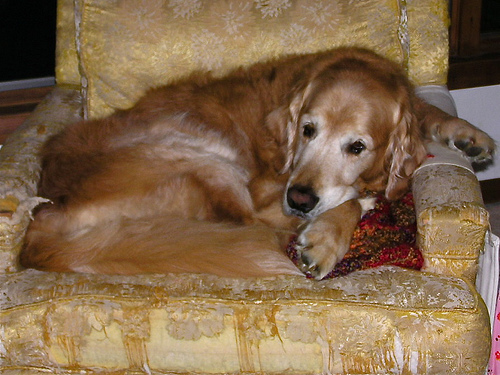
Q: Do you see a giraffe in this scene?
A: No, there are no giraffes.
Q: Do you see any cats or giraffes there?
A: No, there are no giraffes or cats.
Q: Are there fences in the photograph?
A: No, there are no fences.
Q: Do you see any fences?
A: No, there are no fences.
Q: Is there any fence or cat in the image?
A: No, there are no fences or cats.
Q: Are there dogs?
A: Yes, there is a dog.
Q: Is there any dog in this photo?
A: Yes, there is a dog.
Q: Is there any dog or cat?
A: Yes, there is a dog.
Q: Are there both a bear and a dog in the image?
A: No, there is a dog but no bears.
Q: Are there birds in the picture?
A: No, there are no birds.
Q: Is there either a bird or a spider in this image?
A: No, there are no birds or spiders.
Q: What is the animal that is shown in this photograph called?
A: The animal is a dog.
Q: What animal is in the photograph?
A: The animal is a dog.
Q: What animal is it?
A: The animal is a dog.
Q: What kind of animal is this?
A: This is a dog.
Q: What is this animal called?
A: This is a dog.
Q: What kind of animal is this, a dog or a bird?
A: This is a dog.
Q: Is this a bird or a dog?
A: This is a dog.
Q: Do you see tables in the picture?
A: Yes, there is a table.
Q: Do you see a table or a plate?
A: Yes, there is a table.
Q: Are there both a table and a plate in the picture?
A: No, there is a table but no plates.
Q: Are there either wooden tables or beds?
A: Yes, there is a wood table.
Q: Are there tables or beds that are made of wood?
A: Yes, the table is made of wood.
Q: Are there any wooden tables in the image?
A: Yes, there is a wood table.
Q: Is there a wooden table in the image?
A: Yes, there is a wood table.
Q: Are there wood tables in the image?
A: Yes, there is a wood table.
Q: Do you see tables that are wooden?
A: Yes, there is a table that is wooden.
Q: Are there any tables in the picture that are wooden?
A: Yes, there is a table that is wooden.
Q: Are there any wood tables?
A: Yes, there is a table that is made of wood.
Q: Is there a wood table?
A: Yes, there is a table that is made of wood.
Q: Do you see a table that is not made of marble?
A: Yes, there is a table that is made of wood.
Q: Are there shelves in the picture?
A: No, there are no shelves.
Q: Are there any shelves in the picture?
A: No, there are no shelves.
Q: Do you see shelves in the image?
A: No, there are no shelves.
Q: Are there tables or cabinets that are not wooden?
A: No, there is a table but it is wooden.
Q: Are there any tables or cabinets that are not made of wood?
A: No, there is a table but it is made of wood.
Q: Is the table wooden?
A: Yes, the table is wooden.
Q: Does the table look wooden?
A: Yes, the table is wooden.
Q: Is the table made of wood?
A: Yes, the table is made of wood.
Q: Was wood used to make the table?
A: Yes, the table is made of wood.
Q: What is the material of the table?
A: The table is made of wood.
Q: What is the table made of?
A: The table is made of wood.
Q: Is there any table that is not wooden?
A: No, there is a table but it is wooden.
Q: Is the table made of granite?
A: No, the table is made of wood.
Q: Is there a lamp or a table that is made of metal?
A: No, there is a table but it is made of wood.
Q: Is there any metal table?
A: No, there is a table but it is made of wood.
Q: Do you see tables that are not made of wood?
A: No, there is a table but it is made of wood.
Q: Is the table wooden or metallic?
A: The table is wooden.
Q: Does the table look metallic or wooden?
A: The table is wooden.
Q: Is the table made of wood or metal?
A: The table is made of wood.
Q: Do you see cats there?
A: No, there are no cats.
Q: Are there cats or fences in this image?
A: No, there are no cats or fences.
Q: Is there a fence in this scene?
A: No, there are no fences.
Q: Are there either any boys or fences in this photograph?
A: No, there are no fences or boys.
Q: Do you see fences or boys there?
A: No, there are no fences or boys.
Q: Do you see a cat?
A: No, there are no cats.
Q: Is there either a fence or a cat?
A: No, there are no cats or fences.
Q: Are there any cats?
A: No, there are no cats.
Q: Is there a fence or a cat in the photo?
A: No, there are no cats or fences.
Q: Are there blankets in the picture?
A: Yes, there is a blanket.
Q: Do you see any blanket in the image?
A: Yes, there is a blanket.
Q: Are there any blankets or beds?
A: Yes, there is a blanket.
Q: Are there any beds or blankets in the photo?
A: Yes, there is a blanket.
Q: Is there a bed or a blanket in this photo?
A: Yes, there is a blanket.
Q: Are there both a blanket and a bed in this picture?
A: No, there is a blanket but no beds.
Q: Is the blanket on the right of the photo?
A: Yes, the blanket is on the right of the image.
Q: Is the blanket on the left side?
A: No, the blanket is on the right of the image.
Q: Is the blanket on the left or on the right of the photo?
A: The blanket is on the right of the image.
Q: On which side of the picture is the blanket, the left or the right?
A: The blanket is on the right of the image.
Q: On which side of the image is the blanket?
A: The blanket is on the right of the image.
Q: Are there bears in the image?
A: No, there are no bears.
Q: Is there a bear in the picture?
A: No, there are no bears.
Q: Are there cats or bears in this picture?
A: No, there are no bears or cats.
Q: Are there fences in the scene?
A: No, there are no fences.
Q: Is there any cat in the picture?
A: No, there are no cats.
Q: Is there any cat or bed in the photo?
A: No, there are no cats or beds.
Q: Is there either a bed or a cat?
A: No, there are no cats or beds.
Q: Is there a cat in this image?
A: No, there are no cats.